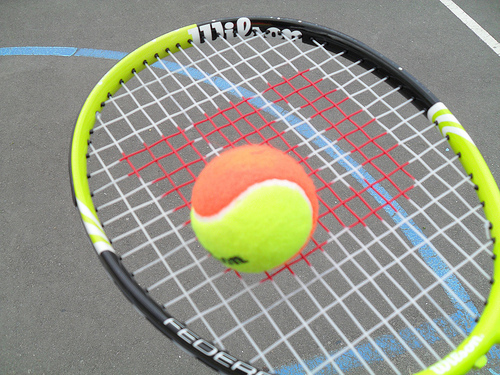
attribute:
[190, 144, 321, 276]
ball — object, subject, photographed, tennis type, made by wilson, orange, yellow, peach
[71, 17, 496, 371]
racquet — tennis type, made by wilson, endorsed, for tennis, yellow, black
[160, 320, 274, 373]
endorsement — by roger federer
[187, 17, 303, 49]
wilson — manufacturer, printed, white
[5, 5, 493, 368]
court — hard, a type, tennis type, called "hard" court", hard court, cement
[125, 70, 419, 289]
"w" — big, wilson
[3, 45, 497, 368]
lines — boundary, blue, light, painted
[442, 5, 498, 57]
line — boundary, white, painted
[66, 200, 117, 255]
design — white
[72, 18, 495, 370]
rim — yellow, black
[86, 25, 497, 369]
strings — white, pink, colored, red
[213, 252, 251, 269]
writing — black, brand name, name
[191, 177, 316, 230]
seam — white, line